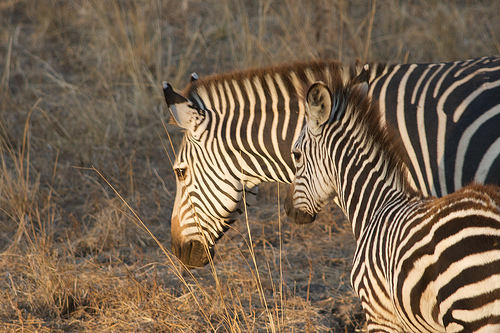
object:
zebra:
[159, 57, 498, 270]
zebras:
[282, 81, 500, 333]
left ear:
[304, 80, 333, 129]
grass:
[0, 0, 499, 333]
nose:
[169, 239, 180, 259]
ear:
[161, 81, 206, 132]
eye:
[292, 150, 302, 163]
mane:
[330, 78, 433, 202]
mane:
[176, 57, 344, 96]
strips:
[456, 313, 500, 333]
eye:
[174, 167, 188, 182]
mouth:
[186, 240, 195, 263]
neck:
[187, 60, 355, 184]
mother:
[159, 55, 499, 267]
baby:
[347, 181, 499, 333]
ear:
[342, 63, 371, 101]